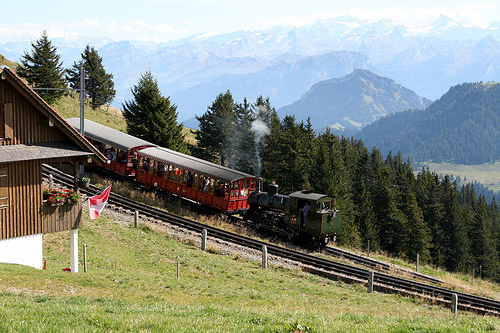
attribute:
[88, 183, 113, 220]
flag — red, white, hanging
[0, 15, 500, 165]
mountains — tall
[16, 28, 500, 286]
trees — green, large, distant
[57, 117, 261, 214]
train — red, green, moving, black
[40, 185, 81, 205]
flowers — red, hanging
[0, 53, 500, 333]
hill — grassy, steep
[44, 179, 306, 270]
rocks — small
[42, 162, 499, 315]
train tracks — for train, brown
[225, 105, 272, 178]
steam — puffing, plumed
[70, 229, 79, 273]
post — wooden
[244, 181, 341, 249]
engine — green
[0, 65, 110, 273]
house — brown